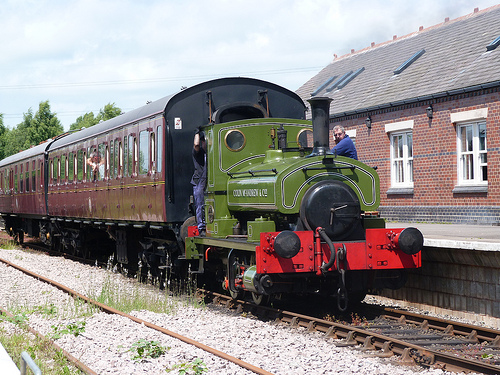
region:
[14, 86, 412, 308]
brown and green train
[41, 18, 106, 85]
white clouds in blue sky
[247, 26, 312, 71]
white clouds in blue sky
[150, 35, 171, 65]
white clouds in blue sky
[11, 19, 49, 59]
white clouds in blue sky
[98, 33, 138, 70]
white clouds in blue sky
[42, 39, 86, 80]
white clouds in blue sky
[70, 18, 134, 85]
white clouds in blue sky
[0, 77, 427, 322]
A train is on the track.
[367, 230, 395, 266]
The train is red.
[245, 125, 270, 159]
The train is green.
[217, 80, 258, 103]
The train is black.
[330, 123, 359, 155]
A man is next to the train.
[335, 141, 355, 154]
The shirt is blue.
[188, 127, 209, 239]
A person stands on the train.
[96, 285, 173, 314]
Grass grows on the tracks.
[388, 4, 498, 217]
A building is next to the tracks.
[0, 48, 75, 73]
The sky is blue.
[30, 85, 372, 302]
old green and brown train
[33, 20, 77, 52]
white clouds in blue sky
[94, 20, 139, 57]
white clouds in blue sky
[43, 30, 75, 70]
white clouds in blue sky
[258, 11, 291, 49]
white clouds in blue sky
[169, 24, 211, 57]
white clouds in blue sky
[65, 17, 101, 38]
white clouds in blue sky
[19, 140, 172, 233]
red side of train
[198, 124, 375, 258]
green engine on train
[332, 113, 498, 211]
red brick wall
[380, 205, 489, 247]
sidewalk is light grey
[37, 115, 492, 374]
train on brown tracks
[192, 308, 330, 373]
light grey gravel near track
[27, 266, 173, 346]
tall and wispy grass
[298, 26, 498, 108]
grey roof on building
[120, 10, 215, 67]
blue and white sky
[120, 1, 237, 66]
white clouds in sky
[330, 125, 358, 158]
Man in a blue shirt and sunglasses on the train.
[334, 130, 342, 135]
The man has dark sunglasses.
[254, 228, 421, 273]
Red section on the font of the train.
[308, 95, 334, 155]
Black smoke stack on the train.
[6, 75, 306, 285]
The train cars are purple.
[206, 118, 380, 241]
Olive green section of the train.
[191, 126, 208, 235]
Man in overalls on the train.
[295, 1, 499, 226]
Train station is made of brick.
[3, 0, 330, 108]
The sky is cloudy.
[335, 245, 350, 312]
Large chain hanging off the front of the train.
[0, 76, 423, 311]
train engine attached to two train cars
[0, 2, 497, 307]
train is beside a red and grey brick building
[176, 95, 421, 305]
train engine has two small circular windows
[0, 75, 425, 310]
tree tops visible above train cars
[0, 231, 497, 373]
patches of weeds growing near train tracks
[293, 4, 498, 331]
building is up on an elevated platform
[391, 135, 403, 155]
glass window on the building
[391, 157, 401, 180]
glass window on the building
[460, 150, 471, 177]
glass window on the building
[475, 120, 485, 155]
glass window on the building